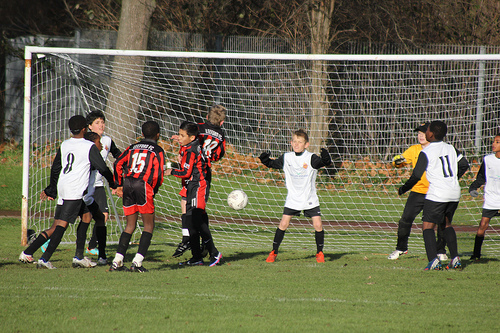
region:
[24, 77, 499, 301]
children playing soccer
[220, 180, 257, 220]
white soccer ball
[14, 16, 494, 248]
white netting of soccer goal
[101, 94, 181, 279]
soccer player in black and red uniform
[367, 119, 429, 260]
soccer goalie wearing yellow shirt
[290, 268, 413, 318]
green grass of soccer field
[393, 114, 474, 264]
soccer player in black and white uniform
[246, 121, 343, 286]
boy wearing orange soccer shoes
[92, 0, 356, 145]
trees in the background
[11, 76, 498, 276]
ten young boys playing soccer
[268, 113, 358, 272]
the goalie looks like he missed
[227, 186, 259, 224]
the soccer ball flying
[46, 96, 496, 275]
the group of the kids playing soccer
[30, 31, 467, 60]
the soccer post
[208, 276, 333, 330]
the grass of the pitch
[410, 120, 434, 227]
the yellow shirt player is actually the goalie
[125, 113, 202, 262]
number 15 on the red team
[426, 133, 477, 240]
number 11 on the white team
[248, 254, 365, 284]
the kids orange shoes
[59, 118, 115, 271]
number 8 on the white team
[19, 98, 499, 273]
group of children playing soccer on soccer field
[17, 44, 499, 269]
white net soccer goal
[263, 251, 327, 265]
orange sneaker cleats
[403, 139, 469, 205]
black and white long sleeve jersey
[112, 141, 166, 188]
orange and black long sleeve jersey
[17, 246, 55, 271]
black and grey sneaker cleats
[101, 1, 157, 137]
brown tree trunk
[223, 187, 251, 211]
white soccer ball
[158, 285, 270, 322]
patch of green grass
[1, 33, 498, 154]
long metal fence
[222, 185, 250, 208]
The white soccer ball.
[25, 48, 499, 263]
The soccer net behind the players.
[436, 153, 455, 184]
The number 11 on the boy's shirt.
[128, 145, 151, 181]
The number 15 on the boy's shirt.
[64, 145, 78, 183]
The number 8 on the boy's shirt.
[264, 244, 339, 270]
The red sneakers the player is wearing.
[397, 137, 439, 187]
The yellow shirt the player is wearing.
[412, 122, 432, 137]
The black hat the player in the yellow shirt is wearing.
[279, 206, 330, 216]
The black shorts worn by the player in red sneakers.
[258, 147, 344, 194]
The white and black shirt the player in red sneakers is wearing.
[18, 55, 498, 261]
A bunch of boys playing soccer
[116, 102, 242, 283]
The boys uniforms are black and red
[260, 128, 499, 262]
The boys uniforms are black and white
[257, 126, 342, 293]
The boy's shoes are orange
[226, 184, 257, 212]
The ball is white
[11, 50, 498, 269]
The net is large and white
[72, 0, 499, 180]
there are trees in the background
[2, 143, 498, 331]
The grass is green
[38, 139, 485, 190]
There are leaves on the ground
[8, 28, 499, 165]
There is a wooden fence